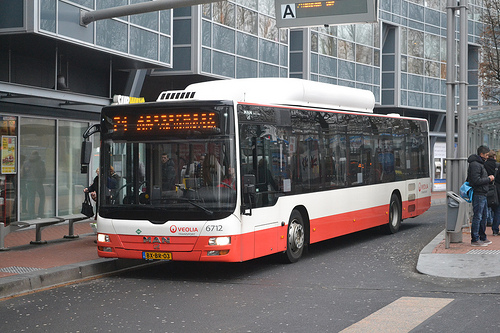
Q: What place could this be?
A: It is a street.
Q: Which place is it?
A: It is a street.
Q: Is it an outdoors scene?
A: Yes, it is outdoors.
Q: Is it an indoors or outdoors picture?
A: It is outdoors.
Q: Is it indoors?
A: No, it is outdoors.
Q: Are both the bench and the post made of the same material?
A: No, the bench is made of cement and the post is made of metal.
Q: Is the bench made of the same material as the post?
A: No, the bench is made of cement and the post is made of metal.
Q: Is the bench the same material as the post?
A: No, the bench is made of cement and the post is made of metal.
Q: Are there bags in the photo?
A: Yes, there is a bag.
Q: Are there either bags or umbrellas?
A: Yes, there is a bag.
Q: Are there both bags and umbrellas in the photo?
A: No, there is a bag but no umbrellas.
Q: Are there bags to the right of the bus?
A: Yes, there is a bag to the right of the bus.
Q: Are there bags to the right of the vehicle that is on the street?
A: Yes, there is a bag to the right of the bus.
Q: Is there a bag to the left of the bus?
A: No, the bag is to the right of the bus.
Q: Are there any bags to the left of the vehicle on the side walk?
A: No, the bag is to the right of the bus.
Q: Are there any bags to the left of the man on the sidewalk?
A: Yes, there is a bag to the left of the man.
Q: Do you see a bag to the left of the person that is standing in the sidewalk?
A: Yes, there is a bag to the left of the man.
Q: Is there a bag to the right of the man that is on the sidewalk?
A: No, the bag is to the left of the man.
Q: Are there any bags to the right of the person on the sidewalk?
A: No, the bag is to the left of the man.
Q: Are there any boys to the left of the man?
A: No, there is a bag to the left of the man.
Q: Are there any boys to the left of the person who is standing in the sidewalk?
A: No, there is a bag to the left of the man.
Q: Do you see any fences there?
A: No, there are no fences.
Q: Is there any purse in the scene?
A: Yes, there is a purse.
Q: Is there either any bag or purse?
A: Yes, there is a purse.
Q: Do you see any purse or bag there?
A: Yes, there is a purse.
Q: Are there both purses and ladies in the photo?
A: No, there is a purse but no ladies.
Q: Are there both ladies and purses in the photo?
A: No, there is a purse but no ladies.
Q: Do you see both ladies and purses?
A: No, there is a purse but no ladies.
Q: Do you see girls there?
A: No, there are no girls.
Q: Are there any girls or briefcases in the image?
A: No, there are no girls or briefcases.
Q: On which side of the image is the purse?
A: The purse is on the left of the image.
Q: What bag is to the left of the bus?
A: The bag is a purse.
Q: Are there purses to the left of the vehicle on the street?
A: Yes, there is a purse to the left of the bus.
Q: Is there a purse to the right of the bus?
A: No, the purse is to the left of the bus.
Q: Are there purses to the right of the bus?
A: No, the purse is to the left of the bus.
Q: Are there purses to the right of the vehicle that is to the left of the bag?
A: No, the purse is to the left of the bus.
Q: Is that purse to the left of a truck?
A: No, the purse is to the left of the bus.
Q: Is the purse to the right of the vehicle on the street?
A: No, the purse is to the left of the bus.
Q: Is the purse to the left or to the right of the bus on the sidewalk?
A: The purse is to the left of the bus.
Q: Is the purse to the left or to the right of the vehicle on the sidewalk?
A: The purse is to the left of the bus.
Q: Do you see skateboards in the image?
A: No, there are no skateboards.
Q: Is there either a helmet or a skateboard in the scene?
A: No, there are no skateboards or helmets.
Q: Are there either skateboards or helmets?
A: No, there are no skateboards or helmets.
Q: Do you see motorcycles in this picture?
A: No, there are no motorcycles.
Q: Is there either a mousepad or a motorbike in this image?
A: No, there are no motorcycles or mouse pads.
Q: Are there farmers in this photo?
A: No, there are no farmers.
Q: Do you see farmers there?
A: No, there are no farmers.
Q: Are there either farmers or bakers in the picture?
A: No, there are no farmers or bakers.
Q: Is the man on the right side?
A: Yes, the man is on the right of the image.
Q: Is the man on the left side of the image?
A: No, the man is on the right of the image.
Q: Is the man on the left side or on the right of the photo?
A: The man is on the right of the image.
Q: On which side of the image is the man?
A: The man is on the right of the image.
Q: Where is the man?
A: The man is on the side walk.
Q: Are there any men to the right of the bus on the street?
A: Yes, there is a man to the right of the bus.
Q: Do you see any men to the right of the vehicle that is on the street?
A: Yes, there is a man to the right of the bus.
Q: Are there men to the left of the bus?
A: No, the man is to the right of the bus.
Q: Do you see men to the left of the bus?
A: No, the man is to the right of the bus.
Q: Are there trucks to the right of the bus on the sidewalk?
A: No, there is a man to the right of the bus.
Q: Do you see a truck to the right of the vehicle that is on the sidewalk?
A: No, there is a man to the right of the bus.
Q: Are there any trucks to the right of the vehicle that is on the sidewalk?
A: No, there is a man to the right of the bus.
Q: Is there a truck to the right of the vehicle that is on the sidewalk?
A: No, there is a man to the right of the bus.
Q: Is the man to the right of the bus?
A: Yes, the man is to the right of the bus.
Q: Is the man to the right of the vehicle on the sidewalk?
A: Yes, the man is to the right of the bus.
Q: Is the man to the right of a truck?
A: No, the man is to the right of the bus.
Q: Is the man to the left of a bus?
A: No, the man is to the right of a bus.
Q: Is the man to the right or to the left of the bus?
A: The man is to the right of the bus.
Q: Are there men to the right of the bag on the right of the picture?
A: Yes, there is a man to the right of the bag.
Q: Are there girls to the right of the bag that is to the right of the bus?
A: No, there is a man to the right of the bag.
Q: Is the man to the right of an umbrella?
A: No, the man is to the right of the bag.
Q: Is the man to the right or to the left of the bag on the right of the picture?
A: The man is to the right of the bag.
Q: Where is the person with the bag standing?
A: The man is standing in the sidewalk.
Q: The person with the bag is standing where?
A: The man is standing in the sidewalk.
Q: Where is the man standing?
A: The man is standing in the sidewalk.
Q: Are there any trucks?
A: No, there are no trucks.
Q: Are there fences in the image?
A: No, there are no fences.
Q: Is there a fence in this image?
A: No, there are no fences.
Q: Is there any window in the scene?
A: Yes, there is a window.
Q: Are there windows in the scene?
A: Yes, there is a window.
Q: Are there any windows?
A: Yes, there is a window.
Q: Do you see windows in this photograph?
A: Yes, there is a window.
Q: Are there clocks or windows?
A: Yes, there is a window.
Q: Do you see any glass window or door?
A: Yes, there is a glass window.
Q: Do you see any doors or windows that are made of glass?
A: Yes, the window is made of glass.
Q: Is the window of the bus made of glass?
A: Yes, the window is made of glass.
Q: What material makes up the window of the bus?
A: The window is made of glass.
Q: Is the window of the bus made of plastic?
A: No, the window is made of glass.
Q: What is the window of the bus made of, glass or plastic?
A: The window is made of glass.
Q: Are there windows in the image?
A: Yes, there are windows.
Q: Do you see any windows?
A: Yes, there are windows.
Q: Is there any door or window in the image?
A: Yes, there are windows.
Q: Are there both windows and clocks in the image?
A: No, there are windows but no clocks.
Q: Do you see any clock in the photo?
A: No, there are no clocks.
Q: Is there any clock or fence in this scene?
A: No, there are no clocks or fences.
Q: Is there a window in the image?
A: Yes, there are windows.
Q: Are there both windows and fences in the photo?
A: No, there are windows but no fences.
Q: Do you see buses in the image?
A: Yes, there is a bus.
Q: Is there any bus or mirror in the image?
A: Yes, there is a bus.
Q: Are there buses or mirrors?
A: Yes, there is a bus.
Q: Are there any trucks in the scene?
A: No, there are no trucks.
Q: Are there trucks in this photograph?
A: No, there are no trucks.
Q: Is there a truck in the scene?
A: No, there are no trucks.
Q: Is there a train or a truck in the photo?
A: No, there are no trucks or trains.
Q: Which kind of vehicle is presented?
A: The vehicle is a bus.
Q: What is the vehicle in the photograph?
A: The vehicle is a bus.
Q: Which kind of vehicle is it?
A: The vehicle is a bus.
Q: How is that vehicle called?
A: This is a bus.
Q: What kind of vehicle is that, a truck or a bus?
A: This is a bus.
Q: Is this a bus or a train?
A: This is a bus.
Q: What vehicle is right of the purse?
A: The vehicle is a bus.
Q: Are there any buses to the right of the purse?
A: Yes, there is a bus to the right of the purse.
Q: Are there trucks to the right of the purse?
A: No, there is a bus to the right of the purse.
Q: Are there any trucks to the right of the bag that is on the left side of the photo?
A: No, there is a bus to the right of the purse.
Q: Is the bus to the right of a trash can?
A: No, the bus is to the right of the purse.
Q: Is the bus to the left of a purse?
A: No, the bus is to the right of a purse.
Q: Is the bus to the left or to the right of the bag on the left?
A: The bus is to the right of the purse.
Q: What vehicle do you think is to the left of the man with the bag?
A: The vehicle is a bus.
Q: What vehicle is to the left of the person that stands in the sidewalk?
A: The vehicle is a bus.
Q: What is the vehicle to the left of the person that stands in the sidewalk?
A: The vehicle is a bus.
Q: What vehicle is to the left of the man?
A: The vehicle is a bus.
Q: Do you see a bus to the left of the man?
A: Yes, there is a bus to the left of the man.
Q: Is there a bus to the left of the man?
A: Yes, there is a bus to the left of the man.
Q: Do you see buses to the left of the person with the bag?
A: Yes, there is a bus to the left of the man.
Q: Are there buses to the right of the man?
A: No, the bus is to the left of the man.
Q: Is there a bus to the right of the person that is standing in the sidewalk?
A: No, the bus is to the left of the man.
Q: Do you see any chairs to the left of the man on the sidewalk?
A: No, there is a bus to the left of the man.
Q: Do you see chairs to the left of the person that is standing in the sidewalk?
A: No, there is a bus to the left of the man.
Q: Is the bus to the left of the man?
A: Yes, the bus is to the left of the man.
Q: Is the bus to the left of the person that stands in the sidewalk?
A: Yes, the bus is to the left of the man.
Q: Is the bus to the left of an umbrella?
A: No, the bus is to the left of the man.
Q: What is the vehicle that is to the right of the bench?
A: The vehicle is a bus.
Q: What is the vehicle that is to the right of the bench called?
A: The vehicle is a bus.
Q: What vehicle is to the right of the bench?
A: The vehicle is a bus.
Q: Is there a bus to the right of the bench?
A: Yes, there is a bus to the right of the bench.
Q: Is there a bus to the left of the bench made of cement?
A: No, the bus is to the right of the bench.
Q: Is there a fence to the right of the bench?
A: No, there is a bus to the right of the bench.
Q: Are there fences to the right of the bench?
A: No, there is a bus to the right of the bench.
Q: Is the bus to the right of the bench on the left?
A: Yes, the bus is to the right of the bench.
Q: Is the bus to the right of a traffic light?
A: No, the bus is to the right of the bench.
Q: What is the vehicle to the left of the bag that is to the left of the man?
A: The vehicle is a bus.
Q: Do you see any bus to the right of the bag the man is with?
A: No, the bus is to the left of the bag.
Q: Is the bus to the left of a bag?
A: Yes, the bus is to the left of a bag.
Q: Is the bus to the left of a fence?
A: No, the bus is to the left of a bag.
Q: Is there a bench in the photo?
A: Yes, there is a bench.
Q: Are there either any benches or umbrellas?
A: Yes, there is a bench.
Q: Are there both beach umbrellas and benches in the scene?
A: No, there is a bench but no beach umbrellas.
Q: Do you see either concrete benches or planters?
A: Yes, there is a concrete bench.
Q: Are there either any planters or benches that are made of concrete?
A: Yes, the bench is made of concrete.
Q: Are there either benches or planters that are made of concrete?
A: Yes, the bench is made of concrete.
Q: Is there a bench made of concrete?
A: Yes, there is a bench that is made of concrete.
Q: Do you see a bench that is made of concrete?
A: Yes, there is a bench that is made of concrete.